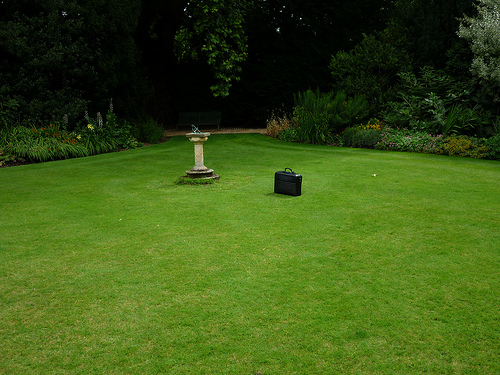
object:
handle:
[283, 167, 293, 172]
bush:
[379, 66, 492, 135]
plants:
[279, 126, 301, 140]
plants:
[132, 114, 166, 142]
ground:
[59, 199, 426, 347]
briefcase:
[273, 167, 302, 196]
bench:
[170, 111, 224, 131]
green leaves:
[175, 33, 194, 59]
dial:
[188, 123, 202, 133]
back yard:
[2, 126, 499, 374]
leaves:
[415, 129, 423, 143]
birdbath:
[183, 124, 214, 142]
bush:
[1, 113, 168, 166]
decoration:
[178, 124, 220, 183]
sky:
[268, 3, 305, 38]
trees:
[327, 33, 415, 117]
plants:
[47, 120, 85, 156]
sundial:
[179, 123, 221, 181]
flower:
[87, 122, 97, 131]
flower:
[75, 133, 85, 141]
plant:
[8, 132, 54, 161]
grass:
[2, 132, 498, 372]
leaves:
[214, 78, 227, 96]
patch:
[385, 217, 430, 258]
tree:
[169, 0, 251, 99]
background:
[5, 31, 499, 160]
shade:
[117, 90, 268, 127]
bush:
[265, 104, 499, 161]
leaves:
[70, 58, 90, 81]